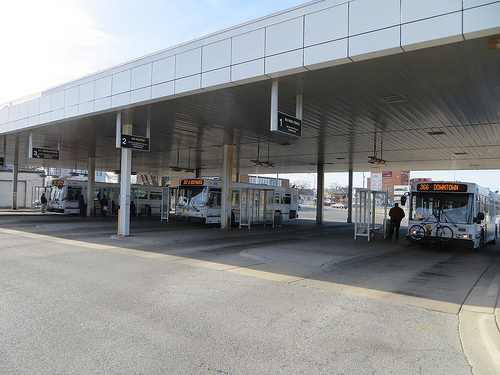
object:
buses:
[171, 179, 297, 223]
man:
[385, 202, 405, 241]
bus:
[397, 179, 497, 250]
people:
[96, 189, 108, 212]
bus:
[43, 181, 168, 219]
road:
[0, 210, 499, 374]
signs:
[120, 133, 152, 151]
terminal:
[0, 0, 498, 294]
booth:
[352, 188, 383, 239]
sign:
[418, 182, 462, 194]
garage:
[0, 168, 50, 209]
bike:
[406, 217, 454, 240]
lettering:
[415, 184, 458, 190]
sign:
[276, 110, 300, 137]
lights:
[374, 157, 387, 166]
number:
[275, 117, 287, 129]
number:
[119, 136, 127, 146]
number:
[30, 148, 40, 158]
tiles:
[227, 29, 267, 67]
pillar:
[117, 131, 134, 235]